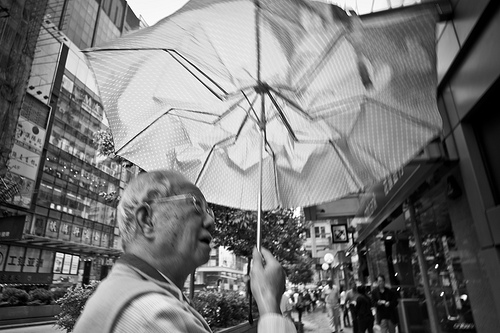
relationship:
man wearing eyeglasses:
[104, 161, 237, 331] [169, 188, 222, 214]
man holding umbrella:
[104, 161, 237, 331] [119, 44, 415, 177]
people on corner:
[311, 271, 405, 331] [275, 287, 467, 325]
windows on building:
[50, 144, 127, 252] [17, 14, 154, 280]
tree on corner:
[221, 199, 282, 323] [275, 287, 467, 325]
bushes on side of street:
[201, 278, 271, 322] [227, 313, 314, 332]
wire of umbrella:
[223, 91, 261, 164] [119, 44, 415, 177]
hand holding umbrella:
[244, 253, 306, 324] [119, 44, 415, 177]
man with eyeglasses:
[104, 161, 237, 331] [169, 188, 222, 214]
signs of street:
[311, 220, 359, 265] [227, 313, 314, 332]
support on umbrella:
[221, 91, 309, 189] [119, 44, 415, 177]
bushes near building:
[201, 278, 271, 322] [17, 14, 154, 280]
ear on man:
[134, 203, 155, 241] [104, 161, 237, 331]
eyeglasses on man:
[169, 188, 222, 214] [104, 161, 237, 331]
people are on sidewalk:
[311, 271, 405, 331] [299, 293, 378, 331]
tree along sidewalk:
[206, 199, 305, 274] [299, 293, 378, 331]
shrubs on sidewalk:
[194, 285, 277, 324] [299, 293, 378, 331]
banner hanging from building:
[24, 123, 60, 200] [17, 14, 154, 280]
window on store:
[406, 205, 447, 279] [345, 188, 484, 332]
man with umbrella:
[104, 161, 237, 331] [119, 44, 415, 177]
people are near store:
[311, 271, 405, 331] [345, 188, 484, 332]